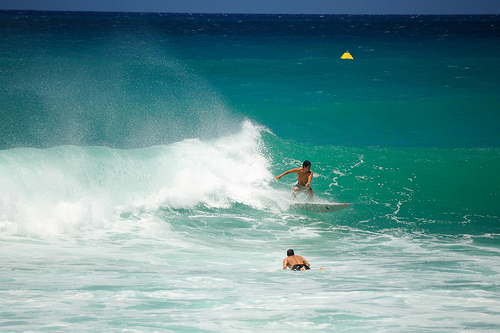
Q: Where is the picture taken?
A: Beach.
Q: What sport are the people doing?
A: Surfing.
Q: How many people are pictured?
A: Two.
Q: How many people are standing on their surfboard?
A: One.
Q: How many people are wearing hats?
A: None.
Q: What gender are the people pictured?
A: Male.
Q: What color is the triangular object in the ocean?
A: Yellow.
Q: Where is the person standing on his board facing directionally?
A: Right.